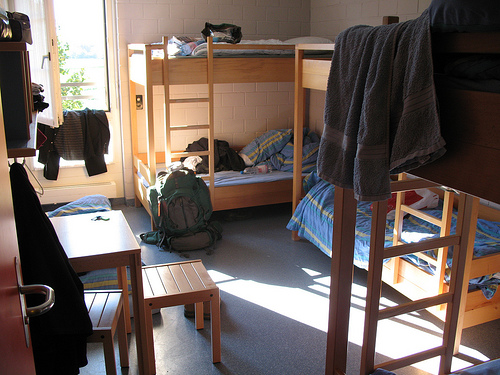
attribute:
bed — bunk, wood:
[324, 24, 498, 371]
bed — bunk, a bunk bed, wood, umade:
[127, 37, 296, 230]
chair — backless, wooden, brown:
[140, 258, 220, 374]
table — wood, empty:
[50, 210, 152, 374]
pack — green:
[157, 164, 215, 252]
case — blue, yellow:
[241, 126, 294, 165]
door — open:
[2, 82, 55, 374]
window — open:
[51, 0, 111, 114]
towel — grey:
[316, 22, 405, 203]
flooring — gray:
[47, 205, 499, 374]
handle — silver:
[20, 283, 55, 318]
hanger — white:
[22, 158, 45, 196]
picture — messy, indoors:
[0, 2, 497, 374]